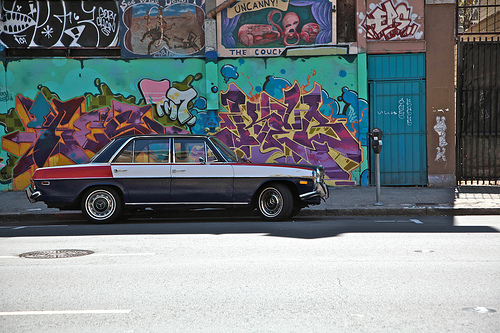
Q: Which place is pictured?
A: It is a road.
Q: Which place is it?
A: It is a road.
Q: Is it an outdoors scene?
A: Yes, it is outdoors.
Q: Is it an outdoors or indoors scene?
A: It is outdoors.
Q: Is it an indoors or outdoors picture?
A: It is outdoors.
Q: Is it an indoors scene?
A: No, it is outdoors.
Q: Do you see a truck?
A: No, there are no trucks.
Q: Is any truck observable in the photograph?
A: No, there are no trucks.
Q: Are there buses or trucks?
A: No, there are no trucks or buses.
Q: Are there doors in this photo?
A: Yes, there is a door.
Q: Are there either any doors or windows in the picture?
A: Yes, there is a door.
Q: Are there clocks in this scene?
A: No, there are no clocks.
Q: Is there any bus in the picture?
A: No, there are no buses.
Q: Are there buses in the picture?
A: No, there are no buses.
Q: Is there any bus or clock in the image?
A: No, there are no buses or clocks.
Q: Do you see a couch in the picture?
A: Yes, there is a couch.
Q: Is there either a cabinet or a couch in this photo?
A: Yes, there is a couch.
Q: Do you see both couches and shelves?
A: No, there is a couch but no shelves.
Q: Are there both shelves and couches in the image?
A: No, there is a couch but no shelves.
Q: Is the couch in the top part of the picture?
A: Yes, the couch is in the top of the image.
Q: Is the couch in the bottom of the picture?
A: No, the couch is in the top of the image.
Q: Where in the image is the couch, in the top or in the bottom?
A: The couch is in the top of the image.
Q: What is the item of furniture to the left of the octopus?
A: The piece of furniture is a couch.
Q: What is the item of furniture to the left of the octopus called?
A: The piece of furniture is a couch.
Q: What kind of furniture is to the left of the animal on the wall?
A: The piece of furniture is a couch.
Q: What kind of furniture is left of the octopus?
A: The piece of furniture is a couch.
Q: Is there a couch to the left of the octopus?
A: Yes, there is a couch to the left of the octopus.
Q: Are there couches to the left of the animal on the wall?
A: Yes, there is a couch to the left of the octopus.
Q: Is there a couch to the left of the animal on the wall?
A: Yes, there is a couch to the left of the octopus.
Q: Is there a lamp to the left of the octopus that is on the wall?
A: No, there is a couch to the left of the octopus.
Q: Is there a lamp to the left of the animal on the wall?
A: No, there is a couch to the left of the octopus.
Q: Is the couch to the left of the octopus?
A: Yes, the couch is to the left of the octopus.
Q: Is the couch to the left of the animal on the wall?
A: Yes, the couch is to the left of the octopus.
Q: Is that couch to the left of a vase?
A: No, the couch is to the left of the octopus.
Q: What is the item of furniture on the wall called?
A: The piece of furniture is a couch.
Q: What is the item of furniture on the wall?
A: The piece of furniture is a couch.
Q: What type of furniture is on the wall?
A: The piece of furniture is a couch.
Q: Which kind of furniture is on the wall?
A: The piece of furniture is a couch.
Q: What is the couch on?
A: The couch is on the wall.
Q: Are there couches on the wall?
A: Yes, there is a couch on the wall.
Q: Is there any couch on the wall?
A: Yes, there is a couch on the wall.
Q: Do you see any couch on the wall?
A: Yes, there is a couch on the wall.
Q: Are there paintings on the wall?
A: No, there is a couch on the wall.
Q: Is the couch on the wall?
A: Yes, the couch is on the wall.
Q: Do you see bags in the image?
A: No, there are no bags.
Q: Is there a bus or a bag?
A: No, there are no bags or buses.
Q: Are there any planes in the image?
A: No, there are no planes.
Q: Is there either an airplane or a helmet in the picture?
A: No, there are no airplanes or helmets.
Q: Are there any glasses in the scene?
A: No, there are no glasses.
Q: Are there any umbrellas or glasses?
A: No, there are no glasses or umbrellas.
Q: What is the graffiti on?
A: The graffiti is on the wall.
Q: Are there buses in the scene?
A: No, there are no buses.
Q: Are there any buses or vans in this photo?
A: No, there are no buses or vans.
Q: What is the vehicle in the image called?
A: The vehicle is a car.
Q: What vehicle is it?
A: The vehicle is a car.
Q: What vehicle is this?
A: This is a car.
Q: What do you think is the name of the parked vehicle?
A: The vehicle is a car.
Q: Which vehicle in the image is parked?
A: The vehicle is a car.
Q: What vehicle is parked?
A: The vehicle is a car.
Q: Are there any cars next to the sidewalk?
A: Yes, there is a car next to the sidewalk.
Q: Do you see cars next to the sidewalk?
A: Yes, there is a car next to the sidewalk.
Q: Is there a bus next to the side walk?
A: No, there is a car next to the side walk.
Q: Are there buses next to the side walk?
A: No, there is a car next to the side walk.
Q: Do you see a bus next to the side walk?
A: No, there is a car next to the side walk.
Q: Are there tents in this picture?
A: No, there are no tents.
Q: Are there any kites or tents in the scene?
A: No, there are no tents or kites.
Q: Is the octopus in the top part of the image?
A: Yes, the octopus is in the top of the image.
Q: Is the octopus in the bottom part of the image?
A: No, the octopus is in the top of the image.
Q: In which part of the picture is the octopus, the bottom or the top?
A: The octopus is in the top of the image.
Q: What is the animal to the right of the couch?
A: The animal is an octopus.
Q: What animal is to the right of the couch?
A: The animal is an octopus.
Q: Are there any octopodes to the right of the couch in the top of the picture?
A: Yes, there is an octopus to the right of the couch.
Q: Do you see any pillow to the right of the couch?
A: No, there is an octopus to the right of the couch.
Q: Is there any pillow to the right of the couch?
A: No, there is an octopus to the right of the couch.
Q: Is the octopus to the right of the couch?
A: Yes, the octopus is to the right of the couch.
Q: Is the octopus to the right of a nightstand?
A: No, the octopus is to the right of the couch.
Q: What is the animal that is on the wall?
A: The animal is an octopus.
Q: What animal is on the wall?
A: The animal is an octopus.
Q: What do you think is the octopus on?
A: The octopus is on the wall.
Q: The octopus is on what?
A: The octopus is on the wall.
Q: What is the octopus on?
A: The octopus is on the wall.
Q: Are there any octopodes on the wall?
A: Yes, there is an octopus on the wall.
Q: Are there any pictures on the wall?
A: No, there is an octopus on the wall.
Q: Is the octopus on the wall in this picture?
A: Yes, the octopus is on the wall.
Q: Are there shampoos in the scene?
A: No, there are no shampoos.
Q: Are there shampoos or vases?
A: No, there are no shampoos or vases.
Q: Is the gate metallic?
A: Yes, the gate is metallic.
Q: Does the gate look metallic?
A: Yes, the gate is metallic.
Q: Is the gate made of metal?
A: Yes, the gate is made of metal.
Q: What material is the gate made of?
A: The gate is made of metal.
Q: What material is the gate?
A: The gate is made of metal.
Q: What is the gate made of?
A: The gate is made of metal.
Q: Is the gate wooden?
A: No, the gate is metallic.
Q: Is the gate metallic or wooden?
A: The gate is metallic.